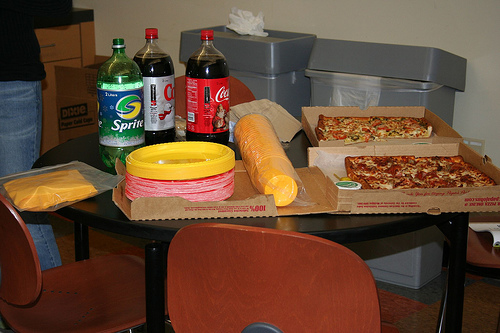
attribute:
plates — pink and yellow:
[142, 140, 259, 222]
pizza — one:
[343, 152, 495, 187]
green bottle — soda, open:
[93, 35, 147, 170]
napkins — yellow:
[18, 144, 104, 224]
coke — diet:
[185, 25, 251, 167]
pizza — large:
[335, 148, 482, 195]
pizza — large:
[315, 106, 444, 146]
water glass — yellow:
[229, 110, 304, 210]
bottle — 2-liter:
[183, 26, 235, 143]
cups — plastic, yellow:
[233, 111, 295, 218]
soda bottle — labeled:
[139, 29, 176, 138]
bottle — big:
[187, 28, 227, 138]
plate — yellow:
[114, 139, 236, 169]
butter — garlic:
[331, 170, 372, 210]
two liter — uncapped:
[96, 36, 144, 166]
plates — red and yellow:
[118, 137, 237, 209]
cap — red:
[200, 27, 215, 39]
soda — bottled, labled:
[185, 27, 229, 143]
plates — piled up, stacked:
[125, 129, 220, 199]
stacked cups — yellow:
[232, 112, 298, 205]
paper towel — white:
[474, 216, 483, 240]